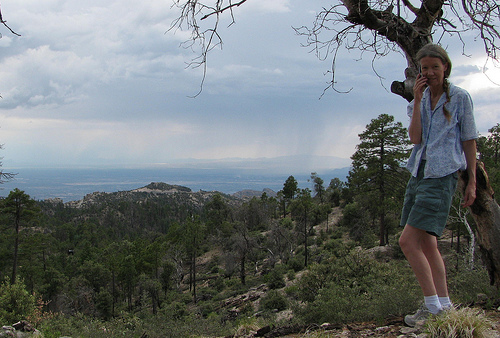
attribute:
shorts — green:
[396, 157, 464, 238]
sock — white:
[422, 294, 444, 314]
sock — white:
[439, 294, 454, 307]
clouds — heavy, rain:
[23, 26, 200, 136]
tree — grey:
[171, 0, 496, 285]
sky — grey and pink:
[33, 33, 281, 155]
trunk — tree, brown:
[456, 161, 499, 286]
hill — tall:
[62, 152, 324, 227]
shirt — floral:
[392, 86, 498, 161]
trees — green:
[4, 119, 498, 336]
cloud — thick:
[2, 41, 145, 106]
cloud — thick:
[9, 1, 198, 48]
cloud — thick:
[162, 45, 283, 91]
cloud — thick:
[200, 0, 359, 33]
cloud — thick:
[453, 48, 497, 88]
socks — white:
[416, 292, 458, 312]